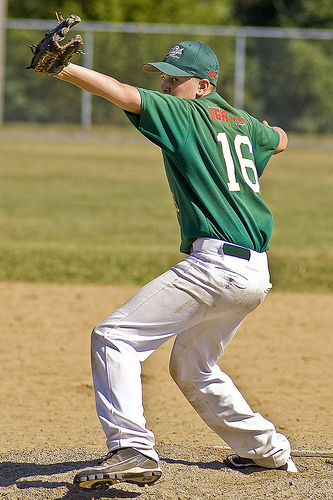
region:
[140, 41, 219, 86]
the green hat on the kid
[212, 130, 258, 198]
the white number on the back of the shirt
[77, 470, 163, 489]
the sole of the cleats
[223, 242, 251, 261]
the green belt in the white pants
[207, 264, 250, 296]
the white pocket on the mans pants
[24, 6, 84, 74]
the brown leather glove on the kids hand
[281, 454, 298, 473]
the pithcher mound under his foot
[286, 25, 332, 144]
the chainlink fence in the outfield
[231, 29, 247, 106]
the pole for the chainlink fence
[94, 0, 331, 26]
the trees behind the outfield fence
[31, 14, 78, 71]
Baseball glove on man's hand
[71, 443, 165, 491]
Brown shoe with yellow sole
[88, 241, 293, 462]
White baseball pants on man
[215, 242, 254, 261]
Green belt around man's waist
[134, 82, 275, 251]
Green baseball jersey on man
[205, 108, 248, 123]
Red sponsor name on man's shirt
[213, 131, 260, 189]
White number on back of jersey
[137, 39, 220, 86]
Red cap on man's head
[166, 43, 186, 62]
Logo on front of cap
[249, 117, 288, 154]
Man's outstretched right arm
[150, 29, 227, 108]
head of a person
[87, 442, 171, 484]
feet of a person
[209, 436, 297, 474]
feet of a person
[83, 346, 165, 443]
leg of a person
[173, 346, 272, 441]
leg of a person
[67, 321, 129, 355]
knee of a person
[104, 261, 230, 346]
thigh of a person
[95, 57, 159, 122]
arm of a person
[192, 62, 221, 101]
ear of a person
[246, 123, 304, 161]
arm of a person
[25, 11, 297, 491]
A pitcher in the process of throwing a ball.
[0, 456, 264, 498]
The pitcher's shadow on the dirt.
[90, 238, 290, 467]
The white pants have dirt stains all over them.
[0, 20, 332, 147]
A fence in the background.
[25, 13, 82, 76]
A baseball glove on the pitcher's hand.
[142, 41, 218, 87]
A green baseball cap.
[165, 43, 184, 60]
The team's logo on the front of the hat.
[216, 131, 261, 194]
The pitcher's team number.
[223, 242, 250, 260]
Part of a green belt.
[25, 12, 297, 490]
The pitcher's uniform is green and white.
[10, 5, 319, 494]
This is a person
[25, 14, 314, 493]
This is a person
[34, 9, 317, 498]
This is a person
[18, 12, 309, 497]
This is a person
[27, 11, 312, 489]
This is a person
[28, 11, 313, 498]
This is a person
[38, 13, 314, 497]
This is a person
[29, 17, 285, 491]
This is a person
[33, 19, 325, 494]
This is a person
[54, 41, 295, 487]
A pitcher of baseball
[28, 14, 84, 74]
The mittens on pitcher's hand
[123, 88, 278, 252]
Green team uniform jersey the player is wearing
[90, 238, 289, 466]
White trousers the player is wearing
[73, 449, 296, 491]
Brown and white shoes on player's feet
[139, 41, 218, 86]
Green baseball cap on the head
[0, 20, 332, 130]
Metal wire chain link fence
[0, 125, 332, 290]
Green grass on the ground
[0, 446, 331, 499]
Brown soil and pebbles under the pitcher's feet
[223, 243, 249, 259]
A green patch on the trouser's waist